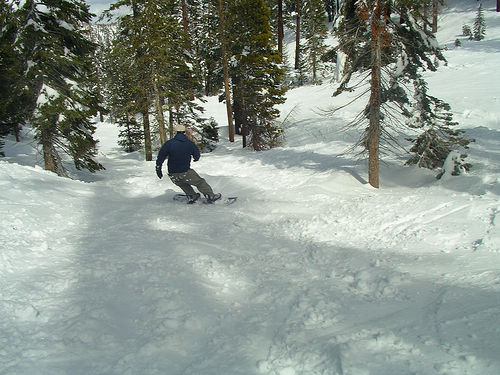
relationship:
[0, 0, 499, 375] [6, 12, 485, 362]
shadows covering ground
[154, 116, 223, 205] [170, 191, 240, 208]
man on snowboard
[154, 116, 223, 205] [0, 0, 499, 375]
man snowboarding down shadows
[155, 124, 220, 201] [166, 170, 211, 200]
man wearing pants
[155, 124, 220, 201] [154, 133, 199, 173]
man wearing a jacket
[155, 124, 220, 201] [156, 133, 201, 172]
man wearing a hoodie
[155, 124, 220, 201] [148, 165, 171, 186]
man wearing glove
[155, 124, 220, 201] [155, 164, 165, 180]
man wearing glove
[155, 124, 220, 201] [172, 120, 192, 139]
man wearing hat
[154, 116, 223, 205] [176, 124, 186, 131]
man wearing hat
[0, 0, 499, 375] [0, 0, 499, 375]
shadows covering shadows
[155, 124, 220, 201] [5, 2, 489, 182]
man snowboarding near trees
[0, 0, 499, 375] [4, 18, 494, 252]
shadows with trees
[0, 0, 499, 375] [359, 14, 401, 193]
shadows with tree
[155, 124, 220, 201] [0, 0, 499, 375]
man in shadows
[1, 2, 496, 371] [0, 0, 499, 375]
shadows in shadows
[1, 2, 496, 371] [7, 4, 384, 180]
shadows of trees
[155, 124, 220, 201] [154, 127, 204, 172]
man wearing hoodie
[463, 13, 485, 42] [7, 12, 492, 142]
pine tree across hill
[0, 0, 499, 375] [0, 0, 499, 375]
shadows on shadows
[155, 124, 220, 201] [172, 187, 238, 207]
man on snowboard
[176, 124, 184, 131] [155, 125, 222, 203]
hat on person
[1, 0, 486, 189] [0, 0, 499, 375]
pine trees are on shadows